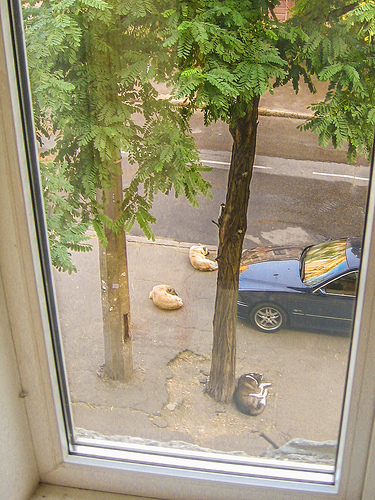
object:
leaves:
[78, 126, 101, 149]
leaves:
[250, 64, 267, 97]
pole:
[85, 16, 134, 380]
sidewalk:
[62, 200, 341, 463]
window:
[317, 270, 359, 299]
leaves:
[205, 73, 233, 98]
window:
[5, 0, 375, 488]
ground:
[126, 229, 209, 415]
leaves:
[120, 59, 148, 91]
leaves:
[177, 36, 193, 57]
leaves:
[192, 162, 213, 202]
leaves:
[318, 125, 332, 146]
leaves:
[45, 28, 66, 50]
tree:
[20, 0, 375, 405]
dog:
[188, 243, 218, 272]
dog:
[149, 284, 183, 310]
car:
[234, 232, 363, 338]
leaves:
[92, 218, 108, 248]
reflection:
[308, 247, 323, 274]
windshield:
[299, 252, 305, 282]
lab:
[149, 285, 184, 311]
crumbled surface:
[149, 346, 256, 442]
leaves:
[75, 122, 99, 148]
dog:
[234, 372, 272, 417]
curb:
[133, 231, 222, 257]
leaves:
[344, 63, 361, 83]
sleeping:
[233, 372, 272, 417]